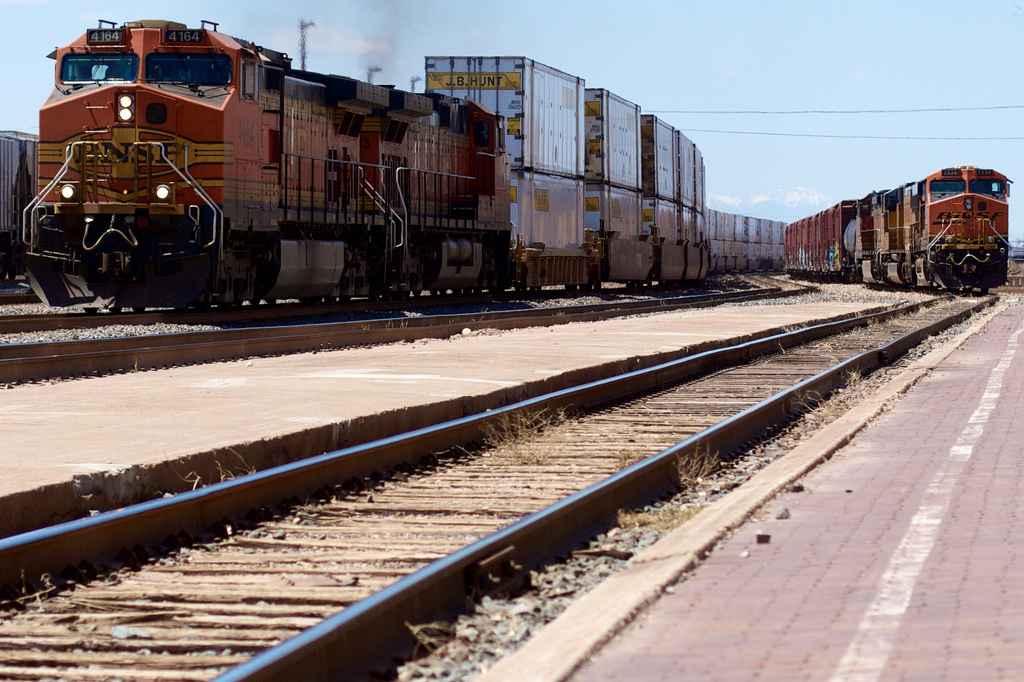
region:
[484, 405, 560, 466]
Dead plant at the center of railings.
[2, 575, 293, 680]
Broken woods at the center of railings.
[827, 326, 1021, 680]
White dash of line on pathway.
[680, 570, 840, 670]
Red bricks on the road.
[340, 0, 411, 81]
Black smoke coming out of train.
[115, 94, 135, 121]
Two rounded lights are on.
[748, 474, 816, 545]
Small stones on the road.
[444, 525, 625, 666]
Small and gray stones beside the railings.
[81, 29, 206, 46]
Numbers in front of the train.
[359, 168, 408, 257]
A white handle bars.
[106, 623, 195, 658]
wood on the track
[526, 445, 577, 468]
wood on the track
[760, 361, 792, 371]
wood on the track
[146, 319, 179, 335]
wood on the track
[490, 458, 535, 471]
wood on the track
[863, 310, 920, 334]
wood on the track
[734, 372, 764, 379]
wood on the track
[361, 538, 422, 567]
wood on the track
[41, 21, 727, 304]
orange train and cars on tracks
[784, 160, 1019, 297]
long train on tracks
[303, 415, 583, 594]
gray metal train tracks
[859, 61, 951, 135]
white clouds in blue sky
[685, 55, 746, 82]
white clouds in blue sky